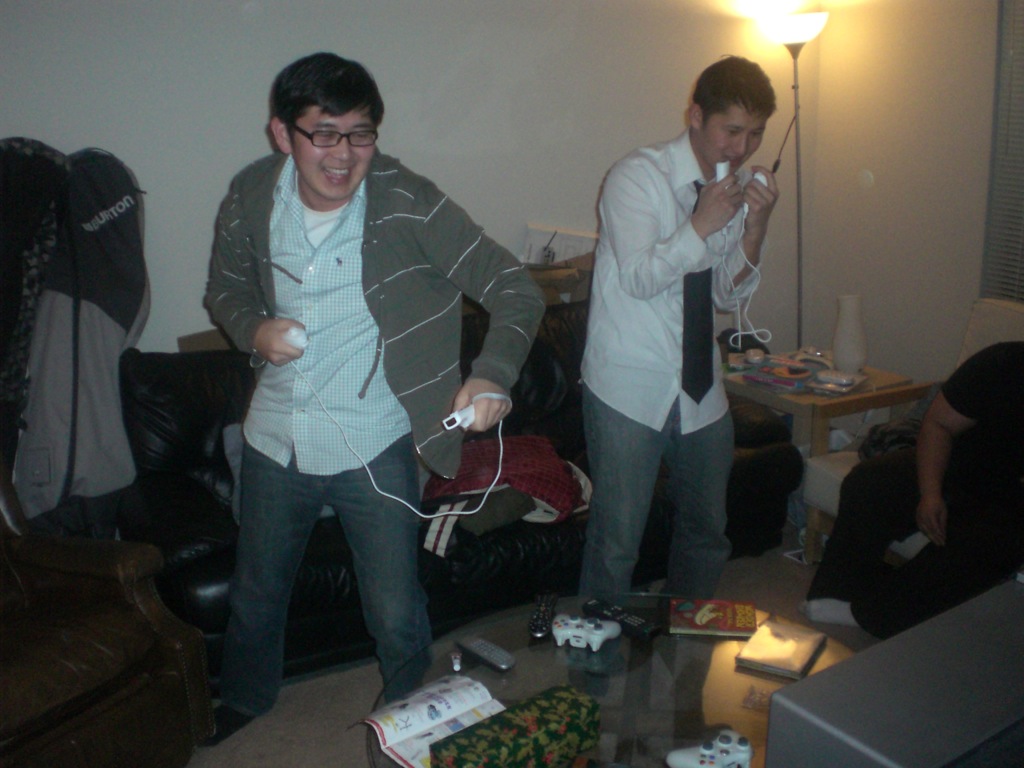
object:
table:
[365, 591, 853, 766]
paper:
[342, 673, 507, 766]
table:
[725, 343, 946, 562]